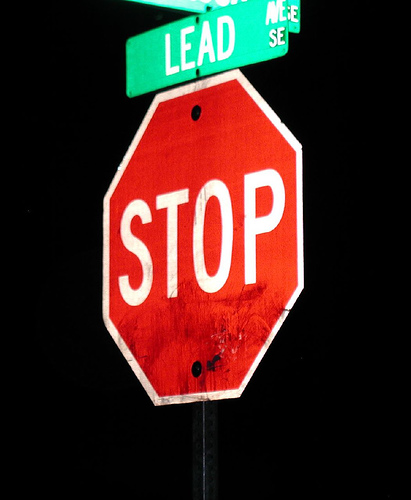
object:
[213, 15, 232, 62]
letters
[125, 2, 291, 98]
street sign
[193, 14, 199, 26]
bolt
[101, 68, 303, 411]
stop sign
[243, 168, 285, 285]
letters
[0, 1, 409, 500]
sky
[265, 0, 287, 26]
ave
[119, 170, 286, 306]
stop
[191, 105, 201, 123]
bolt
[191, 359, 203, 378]
bolt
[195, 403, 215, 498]
pole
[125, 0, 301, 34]
street sign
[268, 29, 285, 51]
se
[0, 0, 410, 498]
background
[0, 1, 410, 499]
photo